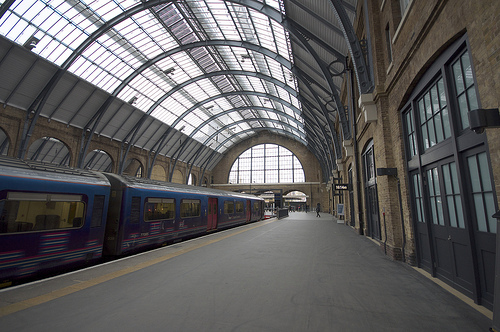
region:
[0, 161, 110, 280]
a colorful train car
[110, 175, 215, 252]
a colorful train car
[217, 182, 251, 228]
a colorful train car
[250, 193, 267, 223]
a colorful train car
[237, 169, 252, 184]
window at the end of the terminal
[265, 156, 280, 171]
window at the end of the terminal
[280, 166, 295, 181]
window at the end of the terminal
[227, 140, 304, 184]
window at the end of the terminal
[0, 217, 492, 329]
a long and empty platform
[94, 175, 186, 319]
A train is visible.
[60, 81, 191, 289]
A train is visible.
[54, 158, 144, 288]
A train is visible.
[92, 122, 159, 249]
A train is visible.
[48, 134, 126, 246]
A train is visible.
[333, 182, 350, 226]
a telephone booth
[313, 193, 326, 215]
a person wearing black is standing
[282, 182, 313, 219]
lots of people walking in background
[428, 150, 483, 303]
a black door with windows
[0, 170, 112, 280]
a blue subway train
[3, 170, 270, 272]
two blue and purple subway trains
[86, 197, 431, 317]
cement walkway in subway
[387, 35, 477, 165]
many windows with brown trim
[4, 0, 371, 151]
an arch dome of windows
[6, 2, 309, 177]
lots of light shining through windows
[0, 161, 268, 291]
the train is blue on top with red and white strips that run along the bottom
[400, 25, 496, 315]
the doors are brown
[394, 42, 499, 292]
the doors have many windows in them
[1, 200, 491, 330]
the loading platform for the train is gray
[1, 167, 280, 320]
there is a yellow caution line close to the train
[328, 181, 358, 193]
there is a sign hanging next to the door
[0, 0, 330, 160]
the celing is an open skylight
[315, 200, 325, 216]
there is a person walking in the background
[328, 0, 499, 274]
the wall is made of brick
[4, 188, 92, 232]
the train has long windows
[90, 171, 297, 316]
A train is visible.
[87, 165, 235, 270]
A train is visible.